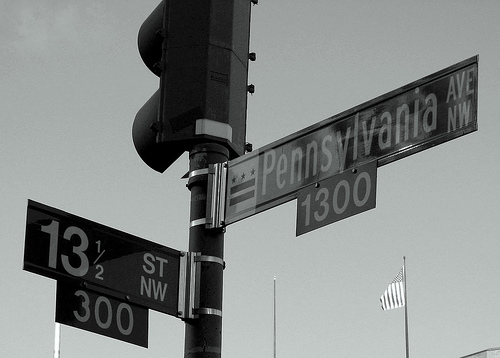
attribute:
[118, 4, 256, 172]
lights — traffic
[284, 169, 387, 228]
sign — 1300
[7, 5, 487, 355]
sky — grey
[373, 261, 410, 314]
flag — American